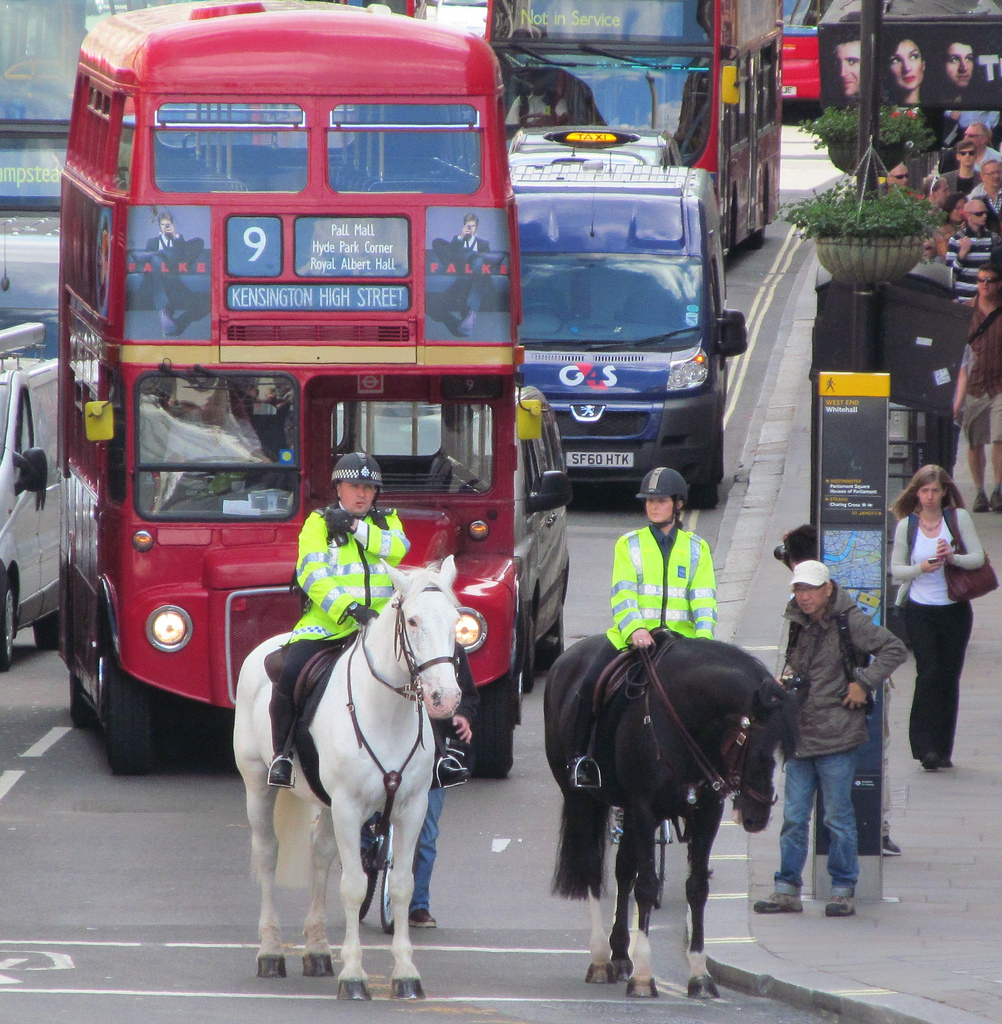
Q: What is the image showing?
A: It is showing a city.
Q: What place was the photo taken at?
A: It was taken at the city.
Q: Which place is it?
A: It is a city.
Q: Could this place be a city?
A: Yes, it is a city.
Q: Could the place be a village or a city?
A: It is a city.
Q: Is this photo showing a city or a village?
A: It is showing a city.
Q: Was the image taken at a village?
A: No, the picture was taken in a city.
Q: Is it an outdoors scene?
A: Yes, it is outdoors.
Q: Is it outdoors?
A: Yes, it is outdoors.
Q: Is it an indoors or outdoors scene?
A: It is outdoors.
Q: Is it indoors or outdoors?
A: It is outdoors.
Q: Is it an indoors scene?
A: No, it is outdoors.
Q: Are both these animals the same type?
A: Yes, all the animals are horses.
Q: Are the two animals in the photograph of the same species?
A: Yes, all the animals are horses.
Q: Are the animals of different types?
A: No, all the animals are horses.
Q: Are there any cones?
A: No, there are no cones.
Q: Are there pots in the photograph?
A: Yes, there is a pot.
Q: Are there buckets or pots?
A: Yes, there is a pot.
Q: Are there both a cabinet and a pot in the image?
A: No, there is a pot but no cabinets.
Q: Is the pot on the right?
A: Yes, the pot is on the right of the image.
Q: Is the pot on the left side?
A: No, the pot is on the right of the image.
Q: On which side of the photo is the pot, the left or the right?
A: The pot is on the right of the image.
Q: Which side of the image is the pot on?
A: The pot is on the right of the image.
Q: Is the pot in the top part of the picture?
A: Yes, the pot is in the top of the image.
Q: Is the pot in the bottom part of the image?
A: No, the pot is in the top of the image.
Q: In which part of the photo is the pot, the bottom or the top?
A: The pot is in the top of the image.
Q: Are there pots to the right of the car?
A: Yes, there is a pot to the right of the car.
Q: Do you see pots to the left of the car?
A: No, the pot is to the right of the car.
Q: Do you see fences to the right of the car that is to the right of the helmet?
A: No, there is a pot to the right of the car.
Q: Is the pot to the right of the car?
A: Yes, the pot is to the right of the car.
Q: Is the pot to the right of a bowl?
A: No, the pot is to the right of the car.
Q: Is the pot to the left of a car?
A: No, the pot is to the right of a car.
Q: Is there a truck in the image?
A: No, there are no trucks.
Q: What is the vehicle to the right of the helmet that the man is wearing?
A: The vehicle is a car.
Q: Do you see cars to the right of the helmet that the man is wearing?
A: Yes, there is a car to the right of the helmet.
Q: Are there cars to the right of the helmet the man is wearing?
A: Yes, there is a car to the right of the helmet.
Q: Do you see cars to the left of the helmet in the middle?
A: No, the car is to the right of the helmet.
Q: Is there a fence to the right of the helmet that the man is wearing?
A: No, there is a car to the right of the helmet.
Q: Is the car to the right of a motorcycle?
A: No, the car is to the right of a helmet.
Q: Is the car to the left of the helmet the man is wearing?
A: No, the car is to the right of the helmet.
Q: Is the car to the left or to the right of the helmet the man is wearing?
A: The car is to the right of the helmet.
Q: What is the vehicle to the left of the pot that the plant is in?
A: The vehicle is a car.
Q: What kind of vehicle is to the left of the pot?
A: The vehicle is a car.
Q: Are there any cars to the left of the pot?
A: Yes, there is a car to the left of the pot.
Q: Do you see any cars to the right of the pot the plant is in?
A: No, the car is to the left of the pot.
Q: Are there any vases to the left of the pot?
A: No, there is a car to the left of the pot.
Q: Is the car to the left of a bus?
A: No, the car is to the left of the pot.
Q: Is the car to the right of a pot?
A: No, the car is to the left of a pot.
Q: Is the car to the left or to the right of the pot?
A: The car is to the left of the pot.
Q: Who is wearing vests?
A: The officers are wearing vests.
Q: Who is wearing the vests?
A: The officers are wearing vests.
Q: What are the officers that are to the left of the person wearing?
A: The officers are wearing vests.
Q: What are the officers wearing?
A: The officers are wearing vests.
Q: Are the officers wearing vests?
A: Yes, the officers are wearing vests.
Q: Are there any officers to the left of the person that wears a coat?
A: Yes, there are officers to the left of the person.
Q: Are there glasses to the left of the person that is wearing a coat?
A: No, there are officers to the left of the person.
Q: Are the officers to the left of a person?
A: Yes, the officers are to the left of a person.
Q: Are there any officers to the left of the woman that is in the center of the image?
A: Yes, there are officers to the left of the woman.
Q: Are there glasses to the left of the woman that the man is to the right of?
A: No, there are officers to the left of the woman.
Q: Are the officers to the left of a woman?
A: Yes, the officers are to the left of a woman.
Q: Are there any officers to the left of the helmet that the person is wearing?
A: Yes, there are officers to the left of the helmet.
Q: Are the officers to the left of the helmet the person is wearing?
A: Yes, the officers are to the left of the helmet.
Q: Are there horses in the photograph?
A: Yes, there is a horse.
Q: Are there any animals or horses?
A: Yes, there is a horse.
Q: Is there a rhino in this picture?
A: No, there are no rhinos.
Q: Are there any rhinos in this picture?
A: No, there are no rhinos.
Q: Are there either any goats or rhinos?
A: No, there are no rhinos or goats.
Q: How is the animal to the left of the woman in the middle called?
A: The animal is a horse.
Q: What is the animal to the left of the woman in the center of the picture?
A: The animal is a horse.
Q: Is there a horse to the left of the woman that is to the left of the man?
A: Yes, there is a horse to the left of the woman.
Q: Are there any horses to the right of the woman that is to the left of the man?
A: No, the horse is to the left of the woman.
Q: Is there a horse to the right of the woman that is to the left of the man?
A: No, the horse is to the left of the woman.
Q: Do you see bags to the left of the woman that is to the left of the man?
A: No, there is a horse to the left of the woman.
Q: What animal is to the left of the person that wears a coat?
A: The animal is a horse.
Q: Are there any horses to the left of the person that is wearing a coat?
A: Yes, there is a horse to the left of the person.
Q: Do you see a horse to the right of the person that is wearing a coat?
A: No, the horse is to the left of the person.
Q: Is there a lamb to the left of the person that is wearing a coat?
A: No, there is a horse to the left of the person.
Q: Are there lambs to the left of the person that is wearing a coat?
A: No, there is a horse to the left of the person.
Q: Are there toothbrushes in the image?
A: No, there are no toothbrushes.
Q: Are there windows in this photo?
A: Yes, there is a window.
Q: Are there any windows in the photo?
A: Yes, there is a window.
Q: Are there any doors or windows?
A: Yes, there is a window.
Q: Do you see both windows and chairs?
A: No, there is a window but no chairs.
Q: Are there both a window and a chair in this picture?
A: No, there is a window but no chairs.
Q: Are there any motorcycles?
A: No, there are no motorcycles.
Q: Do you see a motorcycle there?
A: No, there are no motorcycles.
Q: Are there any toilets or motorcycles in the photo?
A: No, there are no motorcycles or toilets.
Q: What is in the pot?
A: The plant is in the pot.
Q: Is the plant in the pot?
A: Yes, the plant is in the pot.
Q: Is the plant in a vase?
A: No, the plant is in the pot.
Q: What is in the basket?
A: The plant is in the basket.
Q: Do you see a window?
A: Yes, there is a window.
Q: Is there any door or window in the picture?
A: Yes, there is a window.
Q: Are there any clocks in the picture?
A: No, there are no clocks.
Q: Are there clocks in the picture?
A: No, there are no clocks.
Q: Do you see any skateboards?
A: No, there are no skateboards.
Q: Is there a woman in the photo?
A: Yes, there is a woman.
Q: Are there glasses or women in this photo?
A: Yes, there is a woman.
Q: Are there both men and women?
A: Yes, there are both a woman and a man.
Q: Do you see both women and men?
A: Yes, there are both a woman and a man.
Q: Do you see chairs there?
A: No, there are no chairs.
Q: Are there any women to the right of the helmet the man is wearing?
A: Yes, there is a woman to the right of the helmet.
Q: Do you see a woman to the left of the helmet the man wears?
A: No, the woman is to the right of the helmet.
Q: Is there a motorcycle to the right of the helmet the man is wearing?
A: No, there is a woman to the right of the helmet.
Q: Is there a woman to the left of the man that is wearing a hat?
A: Yes, there is a woman to the left of the man.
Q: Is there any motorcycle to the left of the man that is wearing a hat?
A: No, there is a woman to the left of the man.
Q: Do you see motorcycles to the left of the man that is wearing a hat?
A: No, there is a woman to the left of the man.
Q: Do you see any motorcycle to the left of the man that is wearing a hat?
A: No, there is a woman to the left of the man.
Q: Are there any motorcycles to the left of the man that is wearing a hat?
A: No, there is a woman to the left of the man.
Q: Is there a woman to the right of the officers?
A: Yes, there is a woman to the right of the officers.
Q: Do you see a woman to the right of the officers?
A: Yes, there is a woman to the right of the officers.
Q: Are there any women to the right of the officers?
A: Yes, there is a woman to the right of the officers.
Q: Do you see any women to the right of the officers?
A: Yes, there is a woman to the right of the officers.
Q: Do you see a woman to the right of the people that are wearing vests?
A: Yes, there is a woman to the right of the officers.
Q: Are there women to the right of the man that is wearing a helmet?
A: Yes, there is a woman to the right of the man.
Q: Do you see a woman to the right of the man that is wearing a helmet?
A: Yes, there is a woman to the right of the man.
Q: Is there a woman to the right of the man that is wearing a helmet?
A: Yes, there is a woman to the right of the man.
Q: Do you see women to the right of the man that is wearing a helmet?
A: Yes, there is a woman to the right of the man.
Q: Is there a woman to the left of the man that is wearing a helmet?
A: No, the woman is to the right of the man.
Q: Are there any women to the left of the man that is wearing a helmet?
A: No, the woman is to the right of the man.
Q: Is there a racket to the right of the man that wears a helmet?
A: No, there is a woman to the right of the man.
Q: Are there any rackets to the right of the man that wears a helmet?
A: No, there is a woman to the right of the man.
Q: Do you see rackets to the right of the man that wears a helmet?
A: No, there is a woman to the right of the man.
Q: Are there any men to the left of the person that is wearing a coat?
A: Yes, there is a man to the left of the person.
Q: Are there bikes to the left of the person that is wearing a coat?
A: No, there is a man to the left of the person.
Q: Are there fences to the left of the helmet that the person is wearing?
A: No, there is a man to the left of the helmet.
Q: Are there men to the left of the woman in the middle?
A: Yes, there is a man to the left of the woman.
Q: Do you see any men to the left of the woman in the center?
A: Yes, there is a man to the left of the woman.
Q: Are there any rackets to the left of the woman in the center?
A: No, there is a man to the left of the woman.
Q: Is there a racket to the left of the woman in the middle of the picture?
A: No, there is a man to the left of the woman.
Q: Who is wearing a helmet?
A: The man is wearing a helmet.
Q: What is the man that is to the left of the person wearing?
A: The man is wearing a helmet.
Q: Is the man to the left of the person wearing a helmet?
A: Yes, the man is wearing a helmet.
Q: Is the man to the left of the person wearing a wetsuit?
A: No, the man is wearing a helmet.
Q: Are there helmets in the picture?
A: Yes, there is a helmet.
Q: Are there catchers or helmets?
A: Yes, there is a helmet.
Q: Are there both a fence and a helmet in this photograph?
A: No, there is a helmet but no fences.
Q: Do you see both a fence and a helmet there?
A: No, there is a helmet but no fences.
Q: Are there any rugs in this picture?
A: No, there are no rugs.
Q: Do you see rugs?
A: No, there are no rugs.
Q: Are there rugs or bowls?
A: No, there are no rugs or bowls.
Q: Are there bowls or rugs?
A: No, there are no rugs or bowls.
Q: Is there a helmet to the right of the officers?
A: Yes, there is a helmet to the right of the officers.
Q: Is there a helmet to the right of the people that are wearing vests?
A: Yes, there is a helmet to the right of the officers.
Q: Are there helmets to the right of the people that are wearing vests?
A: Yes, there is a helmet to the right of the officers.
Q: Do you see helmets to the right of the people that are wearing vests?
A: Yes, there is a helmet to the right of the officers.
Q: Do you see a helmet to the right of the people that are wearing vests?
A: Yes, there is a helmet to the right of the officers.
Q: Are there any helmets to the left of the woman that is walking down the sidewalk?
A: Yes, there is a helmet to the left of the woman.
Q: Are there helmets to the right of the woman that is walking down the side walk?
A: No, the helmet is to the left of the woman.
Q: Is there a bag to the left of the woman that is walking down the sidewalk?
A: No, there is a helmet to the left of the woman.